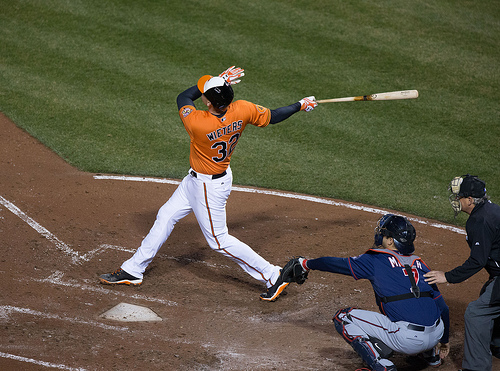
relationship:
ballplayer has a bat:
[99, 64, 317, 304] [319, 90, 420, 105]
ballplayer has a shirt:
[99, 64, 317, 304] [177, 86, 301, 176]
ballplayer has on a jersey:
[99, 64, 317, 304] [177, 100, 272, 174]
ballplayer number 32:
[99, 64, 317, 304] [212, 134, 238, 163]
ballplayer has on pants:
[99, 64, 317, 304] [119, 168, 284, 290]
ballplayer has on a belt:
[99, 64, 317, 304] [189, 167, 232, 178]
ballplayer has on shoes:
[99, 64, 317, 304] [101, 268, 146, 287]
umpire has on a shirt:
[424, 174, 500, 369] [445, 199, 499, 283]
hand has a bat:
[300, 95, 317, 112] [319, 90, 420, 105]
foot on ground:
[100, 267, 144, 287] [0, 1, 499, 370]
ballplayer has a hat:
[99, 64, 317, 304] [195, 73, 232, 107]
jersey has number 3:
[177, 100, 272, 174] [212, 140, 225, 160]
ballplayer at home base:
[99, 64, 317, 304] [101, 302, 161, 325]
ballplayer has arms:
[99, 64, 317, 304] [176, 65, 318, 126]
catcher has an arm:
[278, 214, 450, 369] [298, 254, 371, 280]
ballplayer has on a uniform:
[99, 64, 317, 304] [127, 79, 281, 284]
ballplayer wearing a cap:
[99, 65, 318, 303] [197, 73, 233, 106]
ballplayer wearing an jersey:
[99, 64, 317, 304] [177, 100, 272, 174]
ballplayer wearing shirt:
[99, 64, 317, 304] [177, 86, 301, 176]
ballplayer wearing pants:
[99, 64, 317, 304] [119, 168, 284, 290]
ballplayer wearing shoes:
[99, 64, 317, 304] [101, 268, 146, 287]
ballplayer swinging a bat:
[99, 64, 317, 304] [319, 90, 420, 105]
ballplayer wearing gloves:
[99, 64, 317, 304] [298, 95, 317, 113]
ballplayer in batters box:
[99, 64, 317, 304] [49, 243, 320, 327]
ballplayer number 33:
[99, 64, 317, 304] [211, 134, 238, 161]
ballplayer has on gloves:
[99, 64, 317, 304] [298, 95, 317, 113]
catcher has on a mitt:
[278, 214, 450, 369] [279, 257, 309, 283]